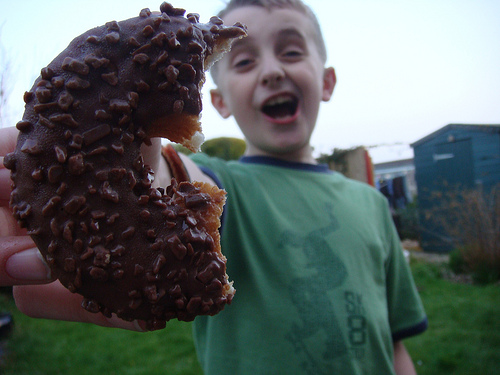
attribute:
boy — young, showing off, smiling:
[1, 2, 433, 375]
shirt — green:
[178, 144, 430, 375]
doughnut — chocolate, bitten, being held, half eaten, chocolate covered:
[0, 0, 254, 333]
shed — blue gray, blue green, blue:
[406, 118, 499, 256]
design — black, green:
[273, 199, 352, 374]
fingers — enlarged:
[2, 118, 152, 336]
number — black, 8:
[344, 313, 370, 349]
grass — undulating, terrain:
[400, 255, 499, 374]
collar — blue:
[236, 152, 335, 177]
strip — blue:
[202, 167, 226, 237]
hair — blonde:
[198, 1, 332, 64]